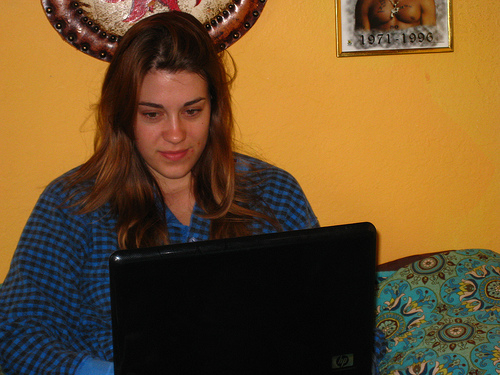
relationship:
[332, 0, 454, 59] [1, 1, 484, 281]
picture on wall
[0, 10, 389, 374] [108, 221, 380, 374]
brunette on computer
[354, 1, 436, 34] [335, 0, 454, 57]
man in picture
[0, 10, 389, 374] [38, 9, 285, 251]
brunette has hair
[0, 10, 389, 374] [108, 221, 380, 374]
brunette holding computer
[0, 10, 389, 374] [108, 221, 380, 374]
brunette working on computer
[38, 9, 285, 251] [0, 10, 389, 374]
hair belonging to brunette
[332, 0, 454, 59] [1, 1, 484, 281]
picture hanging on wall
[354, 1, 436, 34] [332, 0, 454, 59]
man shown in picture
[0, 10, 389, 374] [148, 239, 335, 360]
brunette using computer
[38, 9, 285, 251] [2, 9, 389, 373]
hair belonging to woman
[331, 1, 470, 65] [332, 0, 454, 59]
frame lining picture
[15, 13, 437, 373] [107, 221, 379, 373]
brunette using computer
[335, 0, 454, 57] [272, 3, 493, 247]
picture on wall